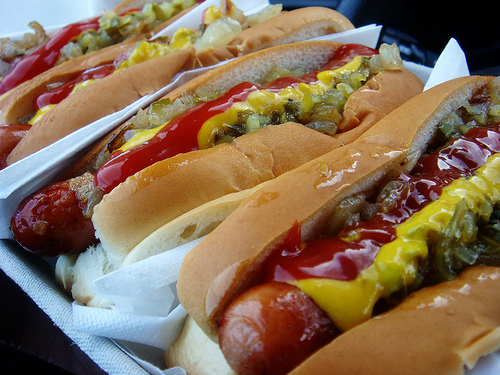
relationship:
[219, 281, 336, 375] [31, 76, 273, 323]
hotdog in line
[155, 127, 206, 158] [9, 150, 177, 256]
ketchup on hotdog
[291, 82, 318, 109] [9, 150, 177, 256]
mustard on hotdog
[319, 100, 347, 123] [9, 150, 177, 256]
relish on hotdog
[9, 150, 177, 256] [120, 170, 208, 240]
hotdog has bun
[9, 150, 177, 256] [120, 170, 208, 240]
hotdog in bun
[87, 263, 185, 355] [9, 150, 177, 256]
napkin around hotdog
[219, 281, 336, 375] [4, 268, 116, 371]
hotdog on plate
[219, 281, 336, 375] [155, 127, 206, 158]
hotdog have ketchup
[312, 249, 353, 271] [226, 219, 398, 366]
ketchup on hotdog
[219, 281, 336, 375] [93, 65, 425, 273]
hotdog in bun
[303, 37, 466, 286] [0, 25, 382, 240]
food in napkin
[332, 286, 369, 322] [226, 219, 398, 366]
mustard on hotdog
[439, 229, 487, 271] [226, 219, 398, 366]
relish on hotdog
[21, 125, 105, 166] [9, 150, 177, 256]
napkin by hotdog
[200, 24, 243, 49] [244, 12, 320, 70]
onions on bun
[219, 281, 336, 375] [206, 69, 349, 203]
hotdog for snack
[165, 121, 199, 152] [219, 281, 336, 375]
ketchup on hotdog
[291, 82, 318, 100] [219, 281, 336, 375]
mustard on hotdog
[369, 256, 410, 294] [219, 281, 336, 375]
mustard on hotdog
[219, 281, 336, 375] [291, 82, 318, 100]
hotdog have mustard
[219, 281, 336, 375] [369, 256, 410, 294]
hotdog have mustard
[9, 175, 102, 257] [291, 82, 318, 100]
hotdog have mustard